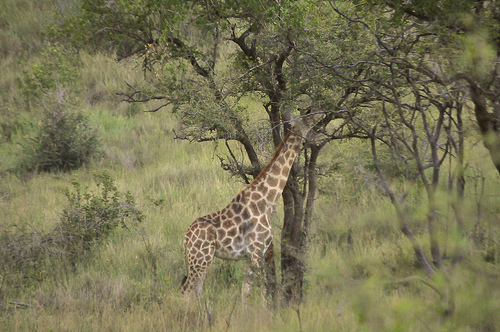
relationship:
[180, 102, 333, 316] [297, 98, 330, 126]
giraffe has head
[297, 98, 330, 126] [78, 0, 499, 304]
head hidden by trees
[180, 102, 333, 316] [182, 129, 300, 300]
giraffe has spots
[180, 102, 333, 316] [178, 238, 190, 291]
giraffe has tail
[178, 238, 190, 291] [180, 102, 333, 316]
tail behind giraffe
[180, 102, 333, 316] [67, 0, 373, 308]
giraffe in front of tree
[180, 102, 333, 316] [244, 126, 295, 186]
giraffe has hair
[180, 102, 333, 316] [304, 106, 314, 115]
giraffe has eye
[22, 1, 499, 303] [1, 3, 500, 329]
bush in field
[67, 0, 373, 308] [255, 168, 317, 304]
tree has base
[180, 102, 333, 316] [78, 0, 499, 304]
giraffe reaching into trees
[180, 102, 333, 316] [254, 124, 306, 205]
giraffe has neck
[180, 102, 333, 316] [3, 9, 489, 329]
giraffe in grass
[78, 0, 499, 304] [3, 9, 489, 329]
trees in grass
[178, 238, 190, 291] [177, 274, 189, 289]
tail has tip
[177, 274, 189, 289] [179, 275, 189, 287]
tip has hair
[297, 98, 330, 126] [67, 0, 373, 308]
head in tree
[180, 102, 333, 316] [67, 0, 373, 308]
giraffe next to tree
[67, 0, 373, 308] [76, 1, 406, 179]
tree has branches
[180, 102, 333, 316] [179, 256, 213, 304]
giraffe has hind leg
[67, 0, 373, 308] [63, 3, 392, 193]
tree has leaves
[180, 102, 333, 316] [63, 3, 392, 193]
giraffe eating leaves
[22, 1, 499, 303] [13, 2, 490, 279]
bush has leaves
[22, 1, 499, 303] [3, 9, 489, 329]
bush in grass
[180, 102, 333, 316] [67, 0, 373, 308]
giraffe reaching into tree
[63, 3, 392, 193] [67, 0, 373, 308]
leaves from tree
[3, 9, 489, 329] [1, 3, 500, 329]
grass in field